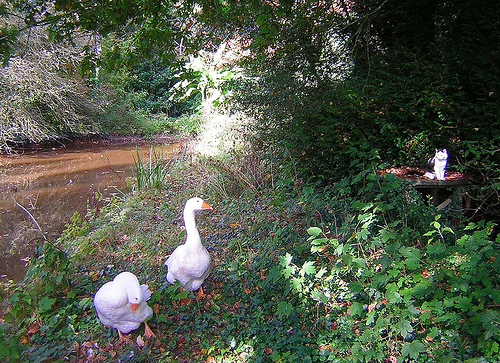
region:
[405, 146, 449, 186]
Black and white cat.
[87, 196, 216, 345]
Two white geese.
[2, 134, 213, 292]
A stream is flowing.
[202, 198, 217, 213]
The goose has an orange beak.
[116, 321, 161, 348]
The goose has two orange feet.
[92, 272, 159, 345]
The goose is cleaning itself.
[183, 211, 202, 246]
The goose has a long neck.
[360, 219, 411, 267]
The leaves are green.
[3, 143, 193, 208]
The sun is shining on the water.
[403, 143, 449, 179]
The cat is sitting.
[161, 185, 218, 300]
goose on the ground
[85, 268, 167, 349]
goose scratching its stomach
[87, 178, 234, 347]
two geese in a garden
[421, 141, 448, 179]
cat on a bird bath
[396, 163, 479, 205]
bird bath in the garden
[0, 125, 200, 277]
river running through a garden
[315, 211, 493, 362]
green foliage on the ground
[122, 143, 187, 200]
tall grass grass growing by the river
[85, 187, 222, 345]
two geese by a creek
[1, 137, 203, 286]
small brown creek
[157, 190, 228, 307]
Duck in the grass.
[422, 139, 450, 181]
Cat on the wood.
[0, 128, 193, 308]
Water behind the ducks.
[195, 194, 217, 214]
Orange beak on duck.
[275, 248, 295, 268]
Green leave on bush.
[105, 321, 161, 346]
Webbed feet on the duck.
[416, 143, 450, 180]
Gray and white hair on cat.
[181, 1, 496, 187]
Tree behind the cat.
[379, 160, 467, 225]
Wood structure under cat.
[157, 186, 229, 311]
White feathers on the bird.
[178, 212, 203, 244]
The neck of the duck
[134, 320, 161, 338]
The foot of the duck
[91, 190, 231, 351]
Two ducks on the ground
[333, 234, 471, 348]
The leaves are the color green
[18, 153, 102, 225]
The water in the pond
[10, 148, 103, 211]
The water is the color brown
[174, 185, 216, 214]
The head of the duck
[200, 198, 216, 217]
The beak of the duck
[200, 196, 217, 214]
The duck's beak is orange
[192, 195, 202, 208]
The eye of the duck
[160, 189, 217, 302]
The goose is white.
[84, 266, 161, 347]
The goose is white.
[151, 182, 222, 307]
The goose is feathered.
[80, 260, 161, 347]
The goose is feathered.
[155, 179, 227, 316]
The goose has an orange beak.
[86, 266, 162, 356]
The goose has an orange beak.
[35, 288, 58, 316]
The leaf is green.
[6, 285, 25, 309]
The leaf is green.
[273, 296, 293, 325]
The leaf is green.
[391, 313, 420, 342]
The leaf is green.